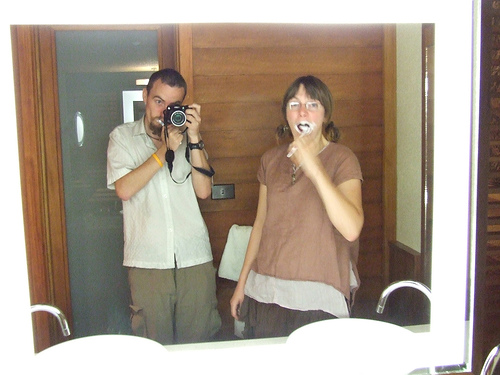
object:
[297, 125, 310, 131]
teeth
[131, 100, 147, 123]
paint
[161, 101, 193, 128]
camera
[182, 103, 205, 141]
hand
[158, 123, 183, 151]
hand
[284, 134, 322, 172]
hand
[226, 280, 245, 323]
hand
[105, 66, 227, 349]
man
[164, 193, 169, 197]
button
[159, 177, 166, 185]
button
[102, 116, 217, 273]
shirt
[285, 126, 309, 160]
toothbrush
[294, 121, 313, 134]
mouth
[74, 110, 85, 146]
light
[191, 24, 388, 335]
wall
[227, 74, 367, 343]
woman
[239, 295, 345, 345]
pants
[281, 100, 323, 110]
clear glasses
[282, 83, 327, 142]
woman's face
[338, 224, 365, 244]
elbow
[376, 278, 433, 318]
faucet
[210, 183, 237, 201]
thermometer